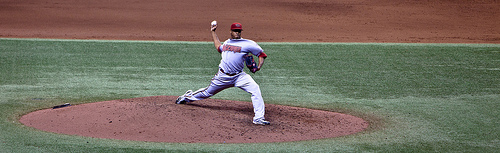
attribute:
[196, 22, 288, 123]
player — baseball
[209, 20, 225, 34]
hand — player's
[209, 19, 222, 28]
ball — tennis, white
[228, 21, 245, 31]
cap — red, baseball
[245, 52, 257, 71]
glove — baseball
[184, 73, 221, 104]
leg — player's, players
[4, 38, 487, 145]
pitch — green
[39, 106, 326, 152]
soil — brown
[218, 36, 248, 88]
jersey — white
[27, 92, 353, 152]
ground — sandy, brown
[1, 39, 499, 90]
grass — green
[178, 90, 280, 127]
feet — apart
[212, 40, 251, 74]
shirt — white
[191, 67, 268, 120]
pants — white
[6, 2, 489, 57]
court — brown, red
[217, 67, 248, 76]
belt — black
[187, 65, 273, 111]
legs — stretched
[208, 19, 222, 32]
baseball — white, round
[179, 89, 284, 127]
shoes — sport